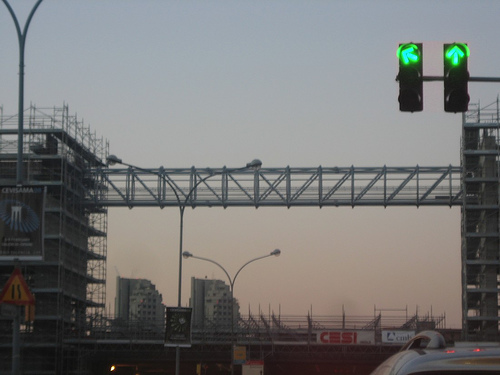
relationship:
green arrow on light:
[399, 45, 416, 63] [398, 41, 422, 118]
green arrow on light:
[446, 43, 466, 67] [443, 42, 467, 119]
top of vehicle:
[390, 336, 466, 350] [395, 363, 497, 374]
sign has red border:
[3, 269, 42, 329] [31, 293, 38, 302]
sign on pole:
[166, 297, 201, 348] [169, 272, 198, 297]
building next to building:
[187, 275, 257, 333] [110, 281, 172, 334]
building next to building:
[110, 281, 172, 334] [187, 275, 257, 333]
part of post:
[9, 348, 28, 358] [7, 306, 39, 357]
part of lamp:
[9, 348, 28, 358] [3, 16, 39, 67]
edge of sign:
[367, 328, 380, 350] [313, 328, 369, 354]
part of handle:
[9, 348, 28, 358] [417, 330, 443, 351]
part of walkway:
[9, 348, 28, 358] [96, 144, 462, 226]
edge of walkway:
[367, 328, 380, 350] [96, 144, 462, 226]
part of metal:
[9, 348, 28, 358] [52, 105, 80, 124]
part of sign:
[9, 348, 28, 358] [313, 328, 369, 354]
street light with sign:
[202, 250, 265, 338] [313, 328, 369, 354]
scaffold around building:
[65, 112, 104, 320] [10, 114, 110, 372]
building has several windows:
[110, 281, 172, 334] [145, 310, 154, 318]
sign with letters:
[313, 328, 369, 354] [324, 333, 359, 344]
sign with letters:
[3, 269, 42, 329] [324, 333, 359, 344]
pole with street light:
[169, 272, 198, 297] [202, 250, 265, 338]